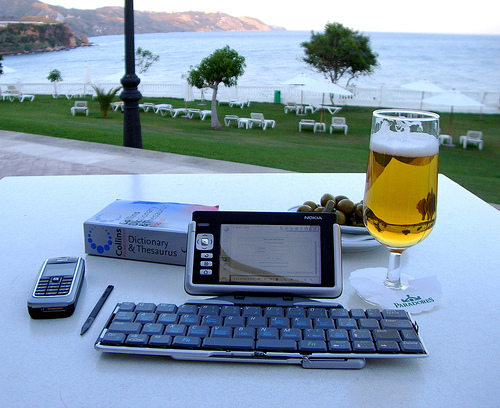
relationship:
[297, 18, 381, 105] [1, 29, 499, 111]
tree near water